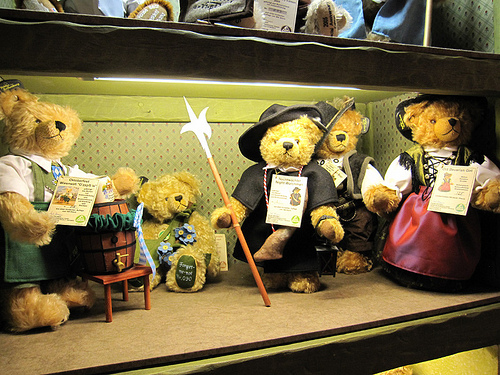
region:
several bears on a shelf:
[7, 78, 497, 305]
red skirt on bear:
[388, 180, 498, 299]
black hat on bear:
[241, 95, 323, 152]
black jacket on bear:
[223, 158, 361, 293]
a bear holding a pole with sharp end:
[166, 92, 300, 322]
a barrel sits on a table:
[73, 190, 153, 305]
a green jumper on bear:
[8, 148, 100, 305]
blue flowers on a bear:
[149, 225, 204, 266]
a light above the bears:
[83, 75, 395, 105]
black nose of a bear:
[276, 135, 294, 156]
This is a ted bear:
[233, 93, 333, 291]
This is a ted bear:
[307, 90, 382, 240]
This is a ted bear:
[386, 90, 494, 271]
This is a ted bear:
[141, 155, 232, 282]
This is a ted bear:
[6, 86, 121, 331]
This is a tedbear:
[9, 74, 90, 341]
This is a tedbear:
[106, 138, 227, 308]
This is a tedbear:
[240, 94, 329, 291]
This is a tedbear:
[315, 89, 403, 266]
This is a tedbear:
[395, 94, 488, 304]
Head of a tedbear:
[13, 92, 80, 170]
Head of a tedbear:
[126, 159, 213, 234]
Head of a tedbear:
[249, 112, 326, 192]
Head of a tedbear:
[318, 93, 371, 173]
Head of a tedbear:
[392, 83, 474, 160]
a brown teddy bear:
[213, 120, 345, 295]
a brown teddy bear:
[135, 170, 215, 286]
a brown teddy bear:
[1, 85, 131, 325]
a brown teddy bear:
[315, 110, 395, 275]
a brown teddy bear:
[386, 95, 496, 280]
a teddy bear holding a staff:
[175, 95, 340, 306]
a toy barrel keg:
[75, 197, 132, 273]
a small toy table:
[65, 262, 152, 320]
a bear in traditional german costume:
[377, 91, 497, 282]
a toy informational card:
[265, 173, 307, 228]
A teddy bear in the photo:
[131, 169, 222, 282]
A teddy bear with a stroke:
[172, 97, 337, 294]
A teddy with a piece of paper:
[3, 94, 93, 324]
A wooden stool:
[93, 251, 165, 310]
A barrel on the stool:
[82, 191, 141, 271]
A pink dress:
[391, 206, 478, 277]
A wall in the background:
[139, 114, 191, 176]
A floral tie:
[165, 219, 195, 249]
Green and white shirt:
[9, 163, 59, 193]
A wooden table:
[176, 312, 257, 339]